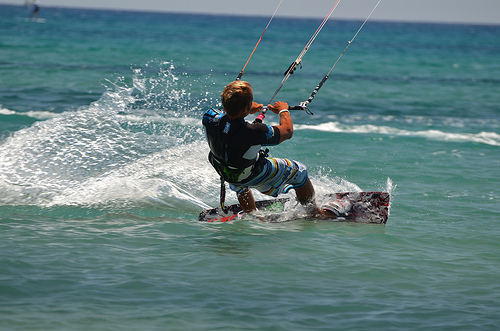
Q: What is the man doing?
A: Water skiing.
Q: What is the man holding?
A: A harness.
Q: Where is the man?
A: In the ocean.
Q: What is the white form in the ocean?
A: Waves.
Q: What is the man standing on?
A: A surfboard.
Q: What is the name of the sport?
A: Surfing.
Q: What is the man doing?
A: Surfing.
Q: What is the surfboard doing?
A: Splashing water.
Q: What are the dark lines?
A: Waves.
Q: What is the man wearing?
A: A wet suit.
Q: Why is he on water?
A: For the sport.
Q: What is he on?
A: A surfboard.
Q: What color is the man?
A: White.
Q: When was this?
A: Daytime.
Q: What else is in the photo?
A: Water.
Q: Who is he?
A: A sportsman.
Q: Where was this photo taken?
A: On the ocean.